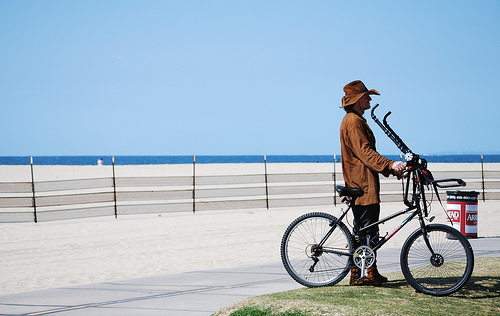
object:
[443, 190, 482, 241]
trash can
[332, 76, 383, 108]
hat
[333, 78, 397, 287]
man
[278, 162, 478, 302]
bike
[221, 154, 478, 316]
up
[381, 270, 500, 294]
shadow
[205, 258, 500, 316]
grass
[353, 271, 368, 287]
pedal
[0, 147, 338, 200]
beach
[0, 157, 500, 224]
fence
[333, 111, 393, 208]
jacket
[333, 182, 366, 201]
seat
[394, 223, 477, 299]
tire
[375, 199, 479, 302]
front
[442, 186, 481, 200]
trash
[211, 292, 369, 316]
patches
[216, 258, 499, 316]
areas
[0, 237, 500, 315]
trail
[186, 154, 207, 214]
pole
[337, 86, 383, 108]
brim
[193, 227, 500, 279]
path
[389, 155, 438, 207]
handlebars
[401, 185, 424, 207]
bar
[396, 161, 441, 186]
handles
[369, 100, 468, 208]
objects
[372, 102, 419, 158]
clarients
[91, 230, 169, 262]
sand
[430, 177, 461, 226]
straps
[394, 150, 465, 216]
frames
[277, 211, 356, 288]
tires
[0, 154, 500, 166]
sea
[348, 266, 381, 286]
shoes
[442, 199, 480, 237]
drawig